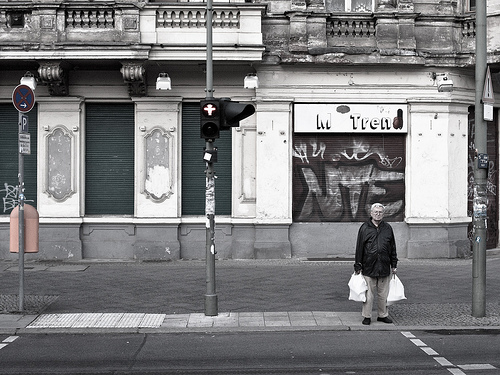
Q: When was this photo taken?
A: During the daytime.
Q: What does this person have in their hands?
A: Bags.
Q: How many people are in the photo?
A: One.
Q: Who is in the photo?
A: One man.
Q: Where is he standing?
A: On a corner.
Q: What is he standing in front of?
A: A building.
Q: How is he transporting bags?
A: Carrying them.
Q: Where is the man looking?
A: At the camera.